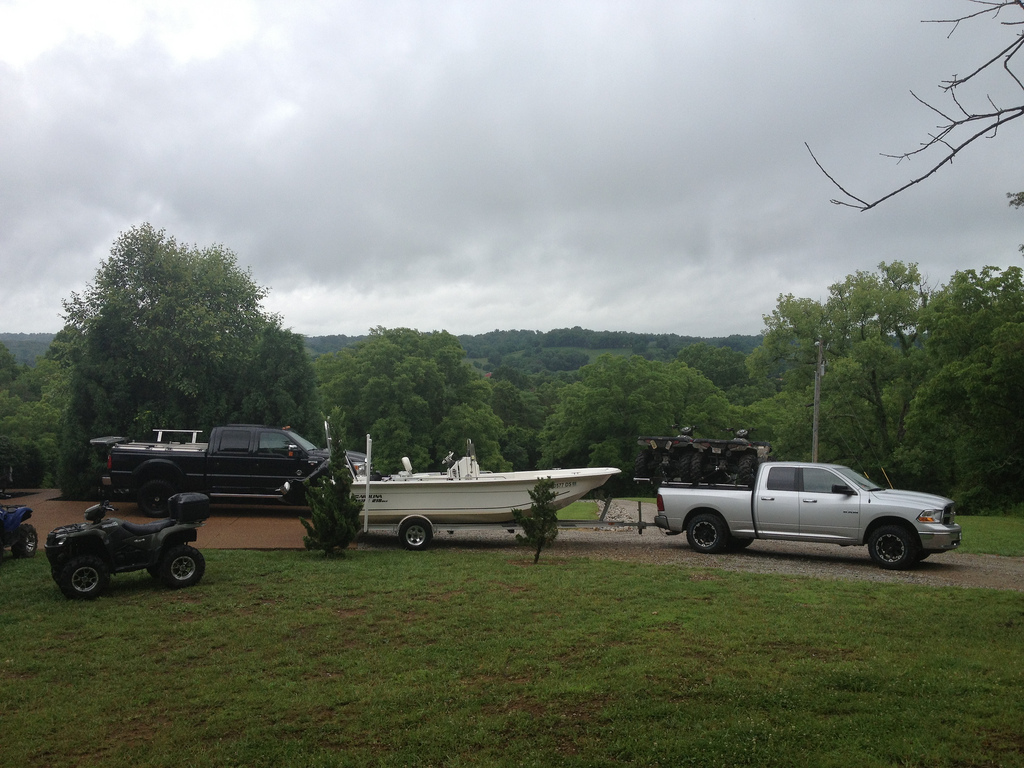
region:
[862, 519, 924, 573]
black tire on vehicle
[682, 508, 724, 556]
black tire on vehicle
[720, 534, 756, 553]
black tire on vehicle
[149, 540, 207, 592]
black tire on vehicle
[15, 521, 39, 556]
black tire on vehicle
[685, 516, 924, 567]
black tires on vehicle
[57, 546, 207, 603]
black tires on vehicle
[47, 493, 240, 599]
Small black sport vehicle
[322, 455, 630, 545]
White striped motor boat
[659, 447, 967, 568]
Silver pick up truck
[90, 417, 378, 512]
Black pick up truck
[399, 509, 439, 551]
Small black and silver wheel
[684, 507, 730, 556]
All black truck tire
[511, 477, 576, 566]
Small green evergreen tree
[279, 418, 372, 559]
Small green evergreen tree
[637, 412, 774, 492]
Atvs sitting on the truck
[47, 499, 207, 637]
four wheeler parked in the grass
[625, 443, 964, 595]
silver truck in the driveway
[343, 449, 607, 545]
boat on a trailer in the driveway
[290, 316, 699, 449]
mountains out in the distance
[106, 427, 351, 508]
black truck parked to the side of the driveway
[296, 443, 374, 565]
small tree by the boat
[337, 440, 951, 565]
silver truck pulling a boat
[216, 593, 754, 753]
green grass in front of the trucks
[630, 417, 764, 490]
four wheelers in the back of the truck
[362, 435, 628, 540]
white boat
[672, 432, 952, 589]
silver truck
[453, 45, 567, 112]
white clouds in the blue sky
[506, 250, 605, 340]
white clouds in the blue sky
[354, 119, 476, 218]
white clouds in the blue sky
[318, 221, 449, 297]
white clouds in the blue sky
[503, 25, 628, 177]
white clouds in the blue sky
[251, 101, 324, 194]
white clouds in the blue sky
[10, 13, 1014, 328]
clouds in the sky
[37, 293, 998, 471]
trees behind the cars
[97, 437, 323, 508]
a large black truck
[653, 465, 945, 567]
a silver truck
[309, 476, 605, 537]
a white boat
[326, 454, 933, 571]
a truck pulling a boat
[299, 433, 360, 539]
a tree in front of the boat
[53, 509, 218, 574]
a four wheeler on the grass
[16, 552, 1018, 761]
grass in front of the truck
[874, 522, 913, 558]
a tire on the truck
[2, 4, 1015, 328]
a gray sky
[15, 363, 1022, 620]
vehicles in the diveway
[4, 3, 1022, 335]
cloud cover in daytime sky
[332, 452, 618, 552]
side of speed boat on trailer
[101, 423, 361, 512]
side of black pickup truck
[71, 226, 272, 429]
green leaves on tree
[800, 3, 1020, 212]
tree branches with no leaves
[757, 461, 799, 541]
truck door with tinted window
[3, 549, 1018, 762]
green grass with patches of dirt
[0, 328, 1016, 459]
green trees in valley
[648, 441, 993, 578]
truck on a street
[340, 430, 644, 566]
boat on a truck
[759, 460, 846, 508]
windows on a truck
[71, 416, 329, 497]
truck near a boat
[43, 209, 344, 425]
tree near a truck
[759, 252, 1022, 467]
trees near a truck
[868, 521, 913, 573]
black tire on the vehicle